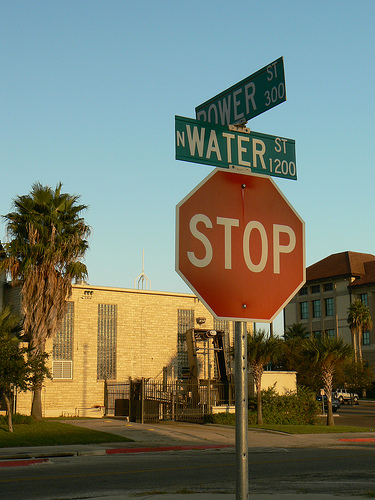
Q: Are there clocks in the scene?
A: No, there are no clocks.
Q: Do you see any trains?
A: No, there are no trains.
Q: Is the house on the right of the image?
A: Yes, the house is on the right of the image.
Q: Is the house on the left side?
A: No, the house is on the right of the image.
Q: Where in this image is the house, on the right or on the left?
A: The house is on the right of the image.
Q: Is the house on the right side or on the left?
A: The house is on the right of the image.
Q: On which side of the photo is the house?
A: The house is on the right of the image.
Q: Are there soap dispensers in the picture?
A: No, there are no soap dispensers.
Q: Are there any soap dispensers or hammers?
A: No, there are no soap dispensers or hammers.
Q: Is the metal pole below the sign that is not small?
A: Yes, the pole is below the sign.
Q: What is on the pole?
A: The sign is on the pole.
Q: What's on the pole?
A: The sign is on the pole.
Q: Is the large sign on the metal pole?
A: Yes, the sign is on the pole.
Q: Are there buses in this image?
A: No, there are no buses.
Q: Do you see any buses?
A: No, there are no buses.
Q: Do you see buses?
A: No, there are no buses.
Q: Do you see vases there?
A: No, there are no vases.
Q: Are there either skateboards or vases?
A: No, there are no vases or skateboards.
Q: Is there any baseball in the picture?
A: No, there are no baseballs.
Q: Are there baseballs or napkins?
A: No, there are no baseballs or napkins.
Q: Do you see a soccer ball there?
A: No, there are no soccer balls.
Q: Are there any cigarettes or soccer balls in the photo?
A: No, there are no soccer balls or cigarettes.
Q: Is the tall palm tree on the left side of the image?
A: Yes, the palm is on the left of the image.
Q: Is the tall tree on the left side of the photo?
A: Yes, the palm is on the left of the image.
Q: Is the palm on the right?
A: No, the palm is on the left of the image.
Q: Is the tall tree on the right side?
A: No, the palm is on the left of the image.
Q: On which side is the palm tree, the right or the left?
A: The palm tree is on the left of the image.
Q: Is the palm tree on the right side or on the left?
A: The palm tree is on the left of the image.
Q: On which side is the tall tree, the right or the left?
A: The palm tree is on the left of the image.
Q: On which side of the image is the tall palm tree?
A: The palm is on the left of the image.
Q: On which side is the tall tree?
A: The palm is on the left of the image.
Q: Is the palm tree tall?
A: Yes, the palm tree is tall.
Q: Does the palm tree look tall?
A: Yes, the palm tree is tall.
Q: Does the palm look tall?
A: Yes, the palm is tall.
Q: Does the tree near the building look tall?
A: Yes, the palm is tall.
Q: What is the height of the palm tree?
A: The palm tree is tall.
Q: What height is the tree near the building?
A: The palm tree is tall.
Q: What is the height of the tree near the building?
A: The palm tree is tall.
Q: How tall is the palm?
A: The palm is tall.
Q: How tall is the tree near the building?
A: The palm is tall.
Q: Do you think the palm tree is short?
A: No, the palm tree is tall.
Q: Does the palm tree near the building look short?
A: No, the palm is tall.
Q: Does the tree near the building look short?
A: No, the palm is tall.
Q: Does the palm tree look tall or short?
A: The palm tree is tall.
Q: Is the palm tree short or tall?
A: The palm tree is tall.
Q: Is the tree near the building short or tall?
A: The palm tree is tall.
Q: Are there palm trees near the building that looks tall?
A: Yes, there is a palm tree near the building.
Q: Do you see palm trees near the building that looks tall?
A: Yes, there is a palm tree near the building.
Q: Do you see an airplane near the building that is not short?
A: No, there is a palm tree near the building.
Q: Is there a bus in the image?
A: No, there are no buses.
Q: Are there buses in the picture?
A: No, there are no buses.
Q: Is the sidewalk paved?
A: Yes, the sidewalk is paved.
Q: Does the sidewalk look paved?
A: Yes, the sidewalk is paved.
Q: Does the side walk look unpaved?
A: No, the side walk is paved.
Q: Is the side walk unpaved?
A: No, the side walk is paved.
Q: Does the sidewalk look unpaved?
A: No, the sidewalk is paved.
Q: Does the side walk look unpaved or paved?
A: The side walk is paved.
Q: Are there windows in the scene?
A: Yes, there is a window.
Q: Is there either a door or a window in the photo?
A: Yes, there is a window.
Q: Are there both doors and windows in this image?
A: No, there is a window but no doors.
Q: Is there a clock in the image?
A: No, there are no clocks.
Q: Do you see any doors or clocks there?
A: No, there are no clocks or doors.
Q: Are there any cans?
A: No, there are no cans.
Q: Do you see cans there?
A: No, there are no cans.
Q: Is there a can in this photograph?
A: No, there are no cans.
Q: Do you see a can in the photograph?
A: No, there are no cans.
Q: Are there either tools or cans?
A: No, there are no cans or tools.